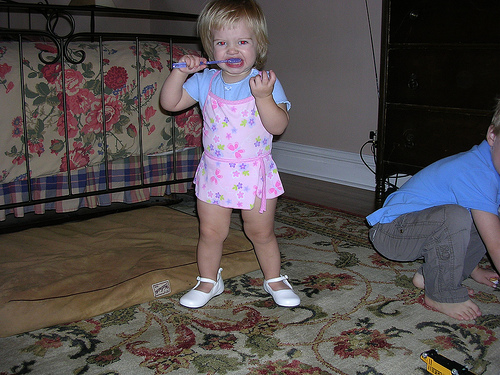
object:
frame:
[0, 0, 207, 235]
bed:
[0, 27, 204, 219]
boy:
[361, 100, 498, 323]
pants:
[367, 204, 486, 302]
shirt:
[180, 67, 292, 109]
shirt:
[365, 141, 498, 228]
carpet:
[1, 183, 498, 373]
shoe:
[180, 266, 225, 308]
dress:
[191, 68, 284, 212]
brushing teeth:
[172, 55, 249, 73]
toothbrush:
[172, 58, 243, 69]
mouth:
[224, 57, 244, 68]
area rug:
[6, 193, 498, 375]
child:
[158, 2, 303, 309]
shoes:
[263, 273, 301, 307]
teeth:
[236, 62, 241, 65]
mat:
[0, 200, 263, 337]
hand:
[178, 54, 207, 74]